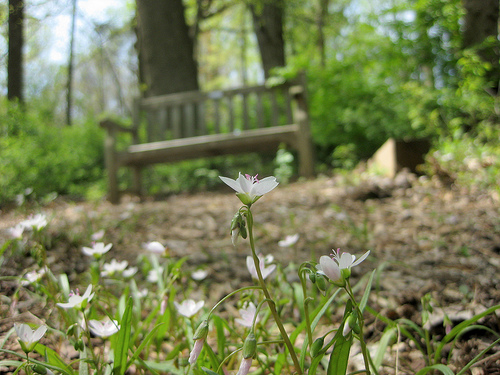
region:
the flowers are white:
[209, 165, 271, 217]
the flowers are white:
[309, 235, 379, 300]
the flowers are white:
[63, 300, 145, 357]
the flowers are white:
[81, 236, 246, 345]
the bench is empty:
[69, 76, 316, 175]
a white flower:
[215, 168, 280, 193]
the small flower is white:
[13, 321, 47, 341]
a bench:
[97, 85, 307, 170]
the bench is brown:
[115, 82, 305, 133]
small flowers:
[62, 292, 125, 335]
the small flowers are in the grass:
[56, 278, 131, 344]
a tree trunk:
[6, 18, 27, 108]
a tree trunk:
[140, 12, 193, 77]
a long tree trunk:
[66, 0, 76, 135]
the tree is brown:
[135, 17, 196, 91]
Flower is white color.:
[215, 157, 313, 207]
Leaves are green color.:
[99, 277, 310, 355]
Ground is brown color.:
[293, 172, 448, 257]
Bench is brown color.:
[80, 78, 325, 175]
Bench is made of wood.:
[96, 83, 328, 178]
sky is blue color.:
[14, 18, 139, 115]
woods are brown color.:
[136, 5, 188, 86]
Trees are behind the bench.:
[118, 8, 305, 118]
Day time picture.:
[31, 35, 465, 358]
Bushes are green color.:
[5, 108, 101, 191]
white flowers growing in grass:
[10, 163, 479, 373]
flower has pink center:
[215, 153, 280, 213]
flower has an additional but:
[219, 200, 261, 245]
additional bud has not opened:
[213, 195, 265, 258]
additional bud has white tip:
[220, 202, 261, 262]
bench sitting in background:
[67, 63, 354, 221]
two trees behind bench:
[115, 0, 321, 192]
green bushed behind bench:
[12, 41, 468, 221]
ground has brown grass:
[60, 173, 498, 321]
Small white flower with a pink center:
[220, 171, 277, 246]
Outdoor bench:
[95, 69, 312, 206]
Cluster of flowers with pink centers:
[1, 171, 376, 373]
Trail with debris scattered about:
[0, 169, 497, 373]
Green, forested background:
[1, 0, 498, 209]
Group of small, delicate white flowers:
[2, 168, 370, 373]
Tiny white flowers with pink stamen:
[0, 169, 371, 374]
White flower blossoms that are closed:
[186, 317, 258, 373]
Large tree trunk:
[133, 1, 199, 161]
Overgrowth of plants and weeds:
[0, 50, 498, 201]